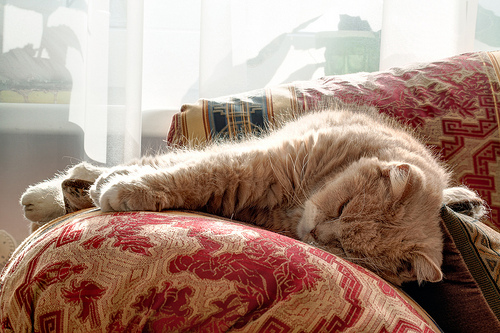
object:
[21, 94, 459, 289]
cat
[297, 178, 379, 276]
face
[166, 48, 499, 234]
cushion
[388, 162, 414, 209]
ear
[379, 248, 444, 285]
left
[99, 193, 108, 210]
paws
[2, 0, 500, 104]
window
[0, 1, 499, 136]
sunlight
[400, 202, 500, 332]
pillow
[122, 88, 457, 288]
fur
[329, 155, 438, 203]
light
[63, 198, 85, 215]
corner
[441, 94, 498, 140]
pattern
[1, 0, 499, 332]
room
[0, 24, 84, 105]
plant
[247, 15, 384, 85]
seal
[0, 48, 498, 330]
couch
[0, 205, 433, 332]
arm rest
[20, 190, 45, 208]
paw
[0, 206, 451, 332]
throw pillow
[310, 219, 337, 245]
nose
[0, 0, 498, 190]
curtain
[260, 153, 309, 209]
whiskers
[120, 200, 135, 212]
claws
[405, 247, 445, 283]
ears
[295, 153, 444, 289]
head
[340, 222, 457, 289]
down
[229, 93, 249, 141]
stripe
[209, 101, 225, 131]
blue stripes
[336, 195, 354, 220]
eyes